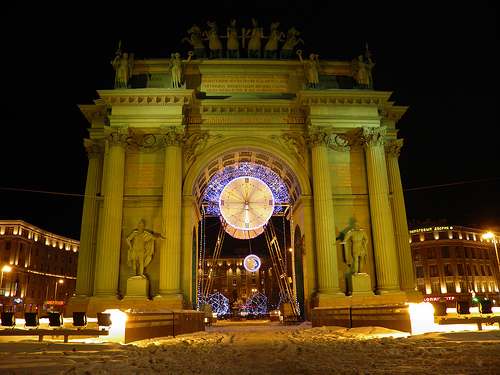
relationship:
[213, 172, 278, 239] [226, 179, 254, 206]
clock has hands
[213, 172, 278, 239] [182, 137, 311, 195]
clock under arch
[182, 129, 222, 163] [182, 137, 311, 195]
figure above arch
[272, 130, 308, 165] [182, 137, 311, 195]
figure above arch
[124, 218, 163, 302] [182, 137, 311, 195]
statue below arch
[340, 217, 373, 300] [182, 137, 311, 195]
statue below arch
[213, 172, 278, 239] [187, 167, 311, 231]
clock in center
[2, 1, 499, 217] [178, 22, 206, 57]
sky behind horse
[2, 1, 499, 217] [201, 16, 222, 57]
sky behind horse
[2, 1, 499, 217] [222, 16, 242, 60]
sky behind horse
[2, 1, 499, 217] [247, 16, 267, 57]
sky behind horse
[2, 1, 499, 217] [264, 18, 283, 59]
sky behind horse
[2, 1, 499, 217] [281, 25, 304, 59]
sky behind horse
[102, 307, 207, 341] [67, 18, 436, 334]
wall leading to monument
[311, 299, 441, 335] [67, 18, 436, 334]
wall leadin to monument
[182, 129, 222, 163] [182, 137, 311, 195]
angel over arch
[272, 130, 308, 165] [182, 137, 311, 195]
angel over arch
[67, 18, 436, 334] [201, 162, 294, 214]
monument has lighting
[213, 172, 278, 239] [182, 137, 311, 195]
clock near arch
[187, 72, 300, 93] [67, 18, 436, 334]
writing on monument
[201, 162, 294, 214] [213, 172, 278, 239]
lights above clock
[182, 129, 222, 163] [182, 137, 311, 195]
angel near arch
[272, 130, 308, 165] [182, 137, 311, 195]
angel near arch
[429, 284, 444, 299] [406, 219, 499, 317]
window on building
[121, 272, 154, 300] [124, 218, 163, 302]
pedestal under statue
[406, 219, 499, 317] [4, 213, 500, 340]
building in background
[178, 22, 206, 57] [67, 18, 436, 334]
horse on top of building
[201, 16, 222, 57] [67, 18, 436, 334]
horse on top of building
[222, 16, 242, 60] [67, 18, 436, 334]
horse on top of building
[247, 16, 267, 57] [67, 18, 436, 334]
horse on top of building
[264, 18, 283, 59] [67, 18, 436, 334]
horse on top of building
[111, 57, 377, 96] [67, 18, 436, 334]
top of building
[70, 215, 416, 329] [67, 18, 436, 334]
bottom of building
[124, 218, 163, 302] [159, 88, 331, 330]
statue on arch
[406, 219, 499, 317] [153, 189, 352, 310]
building behind arch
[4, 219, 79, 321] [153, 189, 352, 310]
building behind arch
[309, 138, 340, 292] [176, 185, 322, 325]
column beside arch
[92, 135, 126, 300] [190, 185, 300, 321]
column beside arch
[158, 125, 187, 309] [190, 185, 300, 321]
pedestal beside arch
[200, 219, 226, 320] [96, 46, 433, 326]
lights illuminating monument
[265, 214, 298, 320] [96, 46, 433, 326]
lights illuminating monument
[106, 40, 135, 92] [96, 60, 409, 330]
statue on monument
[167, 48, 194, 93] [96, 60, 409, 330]
statue on monument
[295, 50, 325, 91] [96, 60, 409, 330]
statue on monument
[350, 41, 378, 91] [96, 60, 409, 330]
statue on monument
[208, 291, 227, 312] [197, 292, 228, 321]
lights decorate tree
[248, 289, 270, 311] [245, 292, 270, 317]
lights decorate tree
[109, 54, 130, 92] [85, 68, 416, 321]
goddess on monument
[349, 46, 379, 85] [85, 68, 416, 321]
goddess on monument